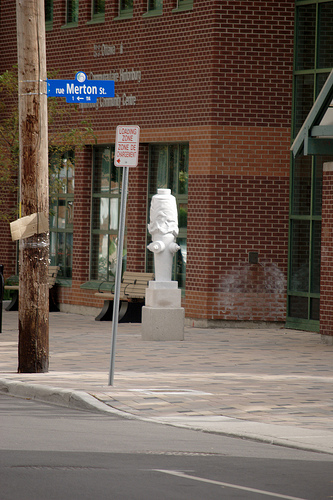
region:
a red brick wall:
[209, 53, 280, 120]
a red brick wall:
[234, 200, 269, 258]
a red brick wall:
[182, 179, 244, 277]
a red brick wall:
[237, 215, 283, 292]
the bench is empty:
[72, 248, 171, 310]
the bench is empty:
[91, 257, 153, 306]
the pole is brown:
[13, 134, 62, 408]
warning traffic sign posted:
[106, 112, 143, 176]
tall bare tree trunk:
[9, 0, 71, 375]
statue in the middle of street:
[140, 177, 202, 361]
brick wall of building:
[220, 15, 282, 114]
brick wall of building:
[212, 191, 283, 253]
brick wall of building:
[220, 123, 287, 181]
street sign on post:
[31, 61, 122, 113]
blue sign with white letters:
[45, 69, 118, 110]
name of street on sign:
[45, 64, 122, 107]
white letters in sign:
[64, 79, 109, 94]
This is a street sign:
[15, 70, 123, 115]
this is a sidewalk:
[39, 354, 182, 455]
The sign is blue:
[57, 84, 132, 130]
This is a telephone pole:
[6, 330, 54, 358]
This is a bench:
[68, 288, 130, 317]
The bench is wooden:
[100, 279, 118, 301]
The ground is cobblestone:
[61, 383, 183, 425]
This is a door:
[287, 273, 304, 299]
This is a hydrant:
[133, 269, 191, 324]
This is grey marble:
[154, 251, 180, 292]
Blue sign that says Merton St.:
[44, 78, 115, 97]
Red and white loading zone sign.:
[114, 124, 139, 167]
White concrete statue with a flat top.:
[141, 187, 185, 341]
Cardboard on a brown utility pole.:
[7, 214, 48, 241]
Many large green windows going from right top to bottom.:
[287, 1, 329, 332]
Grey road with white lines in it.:
[0, 392, 332, 498]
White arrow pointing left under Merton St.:
[74, 95, 83, 100]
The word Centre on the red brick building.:
[120, 91, 137, 106]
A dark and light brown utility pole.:
[13, 1, 50, 373]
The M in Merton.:
[64, 82, 74, 94]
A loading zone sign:
[86, 103, 147, 396]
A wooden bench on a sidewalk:
[63, 240, 154, 328]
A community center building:
[43, 30, 294, 223]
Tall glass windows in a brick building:
[280, 5, 329, 320]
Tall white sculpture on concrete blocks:
[124, 177, 186, 340]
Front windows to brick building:
[46, 113, 149, 300]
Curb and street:
[1, 357, 227, 428]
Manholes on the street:
[12, 431, 231, 487]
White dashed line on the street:
[132, 456, 296, 496]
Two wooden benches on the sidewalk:
[4, 245, 149, 329]